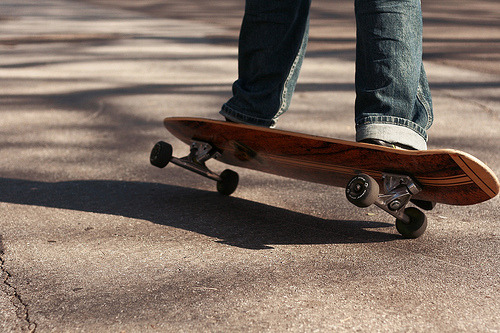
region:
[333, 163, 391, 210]
wheel of the board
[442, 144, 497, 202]
back part of the board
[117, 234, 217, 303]
street next to board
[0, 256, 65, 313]
crack in the street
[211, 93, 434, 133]
feet on the board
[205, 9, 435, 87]
jeans of the person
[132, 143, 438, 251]
four wheels on the board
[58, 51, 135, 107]
shadow on the ground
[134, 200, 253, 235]
shadow of the board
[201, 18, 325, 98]
leg of the person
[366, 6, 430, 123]
folded dark blue denim jeans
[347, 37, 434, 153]
folded dark blue denim jeans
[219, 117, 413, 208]
brown colored printed skateboard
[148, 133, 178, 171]
skateboard wheels are black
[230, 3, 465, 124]
person wears blue jeans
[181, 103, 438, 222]
skateboard is tilted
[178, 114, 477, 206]
skateboard is brown and black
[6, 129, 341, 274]
shadow under skateboard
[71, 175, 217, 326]
concrete is light grey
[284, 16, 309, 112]
blue jeans have seams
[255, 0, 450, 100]
shadows behind person on skateboard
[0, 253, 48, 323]
small crack in concrete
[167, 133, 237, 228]
metal axle between wheels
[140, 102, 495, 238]
a skateboard on a road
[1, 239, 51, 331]
a crack in the road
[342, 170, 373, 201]
a black wheel on a skateboard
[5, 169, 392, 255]
the shadow of a skateboard on the road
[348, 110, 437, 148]
a rolled up pants cuff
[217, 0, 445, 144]
jeans on a skater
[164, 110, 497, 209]
the wood patterned bottom of a skateboard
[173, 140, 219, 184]
a metal tie rod holding the skateboard wheels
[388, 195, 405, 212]
a bolt attaching the wheel unit to the skateboard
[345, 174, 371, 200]
white writing on a wheel